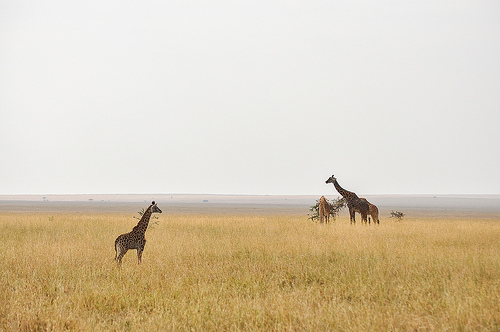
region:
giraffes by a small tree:
[313, 168, 383, 225]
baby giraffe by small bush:
[110, 195, 160, 265]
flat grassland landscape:
[0, 200, 496, 325]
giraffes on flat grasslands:
[0, 170, 495, 330]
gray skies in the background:
[0, 0, 496, 200]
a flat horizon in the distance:
[0, 175, 499, 212]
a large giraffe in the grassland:
[321, 170, 366, 225]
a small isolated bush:
[386, 205, 401, 220]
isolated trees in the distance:
[35, 191, 100, 201]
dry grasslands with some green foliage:
[0, 210, 496, 325]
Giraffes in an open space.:
[61, 145, 467, 290]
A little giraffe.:
[86, 180, 174, 266]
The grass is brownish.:
[210, 243, 486, 325]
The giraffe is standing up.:
[320, 165, 367, 221]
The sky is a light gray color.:
[37, 10, 483, 160]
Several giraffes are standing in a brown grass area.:
[81, 167, 446, 308]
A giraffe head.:
[142, 191, 168, 221]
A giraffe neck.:
[331, 180, 346, 195]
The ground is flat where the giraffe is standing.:
[23, 192, 290, 328]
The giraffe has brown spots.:
[110, 196, 169, 287]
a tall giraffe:
[43, 87, 189, 264]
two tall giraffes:
[47, 60, 464, 278]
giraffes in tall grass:
[28, 79, 455, 326]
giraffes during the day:
[57, 109, 489, 319]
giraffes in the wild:
[75, 67, 446, 315]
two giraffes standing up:
[24, 57, 488, 303]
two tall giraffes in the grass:
[65, 74, 478, 273]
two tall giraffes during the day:
[47, 53, 436, 321]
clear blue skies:
[85, 32, 461, 199]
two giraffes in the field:
[25, 60, 437, 331]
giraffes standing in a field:
[66, 149, 413, 293]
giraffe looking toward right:
[98, 190, 183, 283]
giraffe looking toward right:
[321, 162, 378, 235]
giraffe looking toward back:
[306, 191, 338, 231]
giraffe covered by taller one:
[360, 190, 380, 222]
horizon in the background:
[198, 175, 260, 224]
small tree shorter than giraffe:
[392, 202, 416, 224]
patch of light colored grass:
[259, 249, 350, 317]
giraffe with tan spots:
[106, 185, 172, 274]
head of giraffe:
[144, 195, 166, 217]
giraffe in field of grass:
[97, 191, 172, 278]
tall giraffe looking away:
[324, 173, 381, 228]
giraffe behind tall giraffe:
[362, 203, 394, 216]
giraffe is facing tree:
[315, 196, 330, 219]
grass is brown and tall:
[224, 263, 461, 328]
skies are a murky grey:
[67, 28, 465, 185]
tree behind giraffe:
[308, 199, 348, 216]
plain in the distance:
[15, 183, 486, 205]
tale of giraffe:
[106, 240, 136, 267]